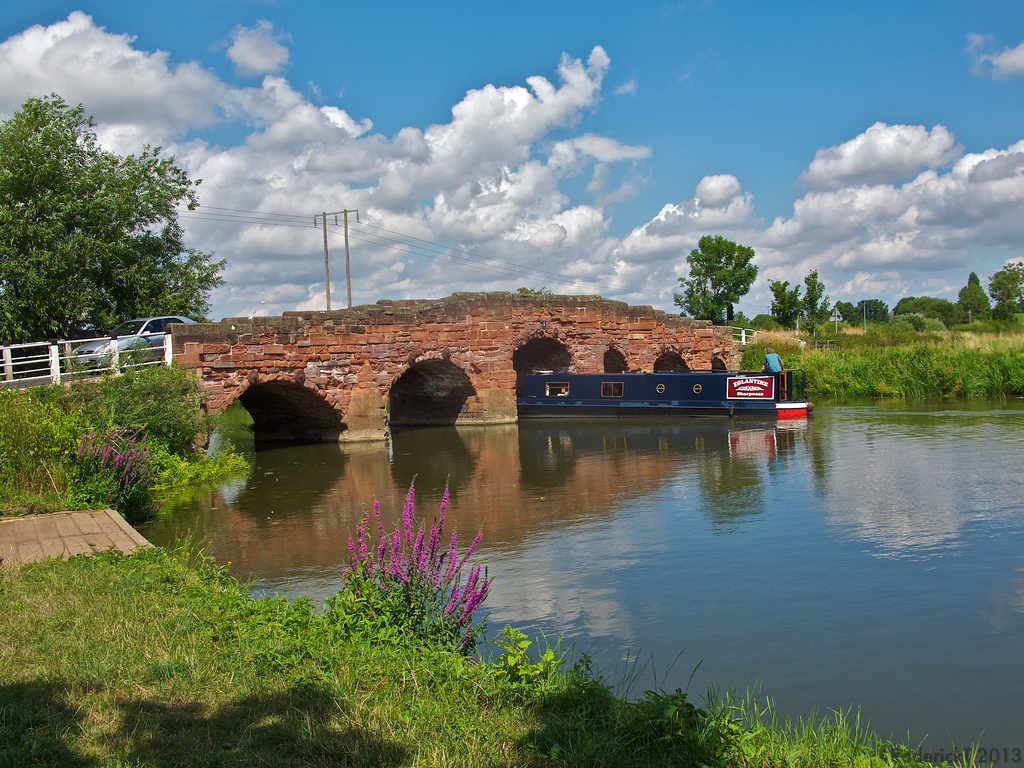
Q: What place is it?
A: It is a river.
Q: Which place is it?
A: It is a river.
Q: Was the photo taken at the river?
A: Yes, it was taken in the river.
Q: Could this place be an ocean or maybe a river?
A: It is a river.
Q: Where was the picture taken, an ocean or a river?
A: It was taken at a river.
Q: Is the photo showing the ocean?
A: No, the picture is showing the river.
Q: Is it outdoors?
A: Yes, it is outdoors.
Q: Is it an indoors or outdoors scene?
A: It is outdoors.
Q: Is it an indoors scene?
A: No, it is outdoors.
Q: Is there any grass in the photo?
A: Yes, there is grass.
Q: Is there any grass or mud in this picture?
A: Yes, there is grass.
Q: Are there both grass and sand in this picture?
A: No, there is grass but no sand.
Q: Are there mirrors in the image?
A: No, there are no mirrors.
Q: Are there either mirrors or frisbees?
A: No, there are no mirrors or frisbees.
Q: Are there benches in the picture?
A: No, there are no benches.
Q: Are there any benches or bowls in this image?
A: No, there are no benches or bowls.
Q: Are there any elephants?
A: No, there are no elephants.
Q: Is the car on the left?
A: Yes, the car is on the left of the image.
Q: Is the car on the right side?
A: No, the car is on the left of the image.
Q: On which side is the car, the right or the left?
A: The car is on the left of the image.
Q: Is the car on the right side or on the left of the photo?
A: The car is on the left of the image.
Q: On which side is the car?
A: The car is on the left of the image.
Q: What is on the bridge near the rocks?
A: The car is on the bridge.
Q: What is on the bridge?
A: The car is on the bridge.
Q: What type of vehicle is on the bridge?
A: The vehicle is a car.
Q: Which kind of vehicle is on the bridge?
A: The vehicle is a car.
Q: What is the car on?
A: The car is on the bridge.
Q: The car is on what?
A: The car is on the bridge.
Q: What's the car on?
A: The car is on the bridge.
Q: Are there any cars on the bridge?
A: Yes, there is a car on the bridge.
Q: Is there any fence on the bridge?
A: No, there is a car on the bridge.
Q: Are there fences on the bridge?
A: No, there is a car on the bridge.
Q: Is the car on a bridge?
A: Yes, the car is on a bridge.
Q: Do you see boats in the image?
A: Yes, there is a boat.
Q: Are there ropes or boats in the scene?
A: Yes, there is a boat.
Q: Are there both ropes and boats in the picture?
A: No, there is a boat but no ropes.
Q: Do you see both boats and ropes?
A: No, there is a boat but no ropes.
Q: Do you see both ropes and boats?
A: No, there is a boat but no ropes.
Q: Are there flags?
A: No, there are no flags.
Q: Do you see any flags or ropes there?
A: No, there are no flags or ropes.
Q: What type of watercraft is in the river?
A: The watercraft is a boat.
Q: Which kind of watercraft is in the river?
A: The watercraft is a boat.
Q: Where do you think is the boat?
A: The boat is in the river.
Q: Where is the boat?
A: The boat is in the river.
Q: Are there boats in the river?
A: Yes, there is a boat in the river.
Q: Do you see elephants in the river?
A: No, there is a boat in the river.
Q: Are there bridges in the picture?
A: Yes, there is a bridge.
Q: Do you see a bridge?
A: Yes, there is a bridge.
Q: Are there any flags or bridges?
A: Yes, there is a bridge.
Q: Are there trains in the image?
A: No, there are no trains.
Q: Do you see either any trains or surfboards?
A: No, there are no trains or surfboards.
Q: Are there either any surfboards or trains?
A: No, there are no trains or surfboards.